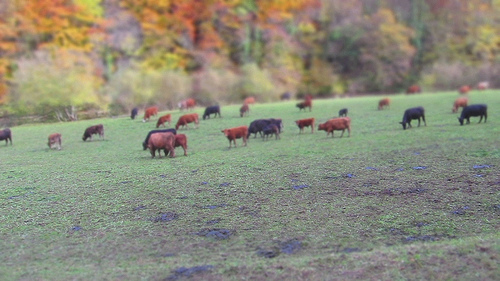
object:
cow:
[458, 104, 489, 127]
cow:
[245, 96, 255, 106]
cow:
[82, 123, 105, 141]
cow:
[404, 85, 424, 96]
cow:
[240, 104, 250, 119]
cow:
[48, 133, 63, 151]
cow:
[339, 108, 349, 117]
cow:
[143, 105, 160, 123]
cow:
[156, 114, 172, 128]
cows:
[459, 85, 473, 93]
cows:
[407, 85, 423, 95]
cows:
[280, 91, 293, 102]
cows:
[179, 100, 187, 110]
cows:
[477, 81, 491, 89]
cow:
[147, 133, 179, 158]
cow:
[223, 126, 249, 147]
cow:
[247, 118, 283, 139]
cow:
[173, 134, 187, 155]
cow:
[0, 129, 15, 145]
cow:
[175, 113, 200, 130]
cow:
[202, 105, 220, 121]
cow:
[398, 106, 427, 130]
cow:
[221, 126, 253, 148]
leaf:
[78, 5, 85, 10]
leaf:
[143, 8, 148, 12]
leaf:
[188, 19, 193, 24]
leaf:
[185, 21, 190, 24]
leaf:
[207, 30, 210, 33]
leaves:
[397, 24, 431, 71]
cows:
[452, 97, 470, 112]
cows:
[296, 95, 314, 112]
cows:
[131, 107, 137, 121]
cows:
[240, 104, 250, 117]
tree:
[0, 0, 500, 128]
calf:
[317, 117, 350, 139]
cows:
[186, 99, 196, 110]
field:
[0, 90, 497, 281]